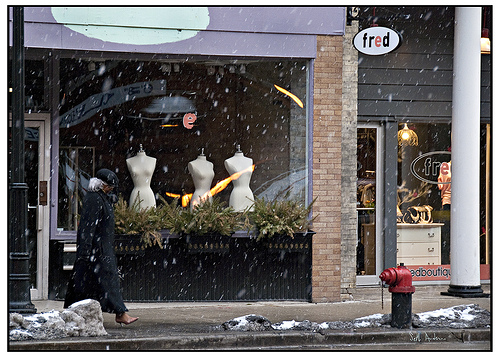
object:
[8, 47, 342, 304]
storefront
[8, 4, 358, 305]
boutique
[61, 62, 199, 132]
reflection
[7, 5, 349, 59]
awning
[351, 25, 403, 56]
shop sign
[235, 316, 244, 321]
snow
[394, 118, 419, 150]
streetlight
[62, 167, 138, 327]
woman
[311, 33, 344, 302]
wall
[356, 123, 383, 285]
door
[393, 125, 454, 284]
storefront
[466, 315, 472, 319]
snow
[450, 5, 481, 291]
column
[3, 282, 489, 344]
sidewalk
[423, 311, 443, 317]
snow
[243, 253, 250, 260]
snow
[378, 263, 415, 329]
fire hydrant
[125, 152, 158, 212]
mannequins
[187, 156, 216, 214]
mannequins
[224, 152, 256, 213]
mannequins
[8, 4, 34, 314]
lamp post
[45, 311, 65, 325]
snow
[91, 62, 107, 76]
snow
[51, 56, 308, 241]
display window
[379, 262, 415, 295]
top